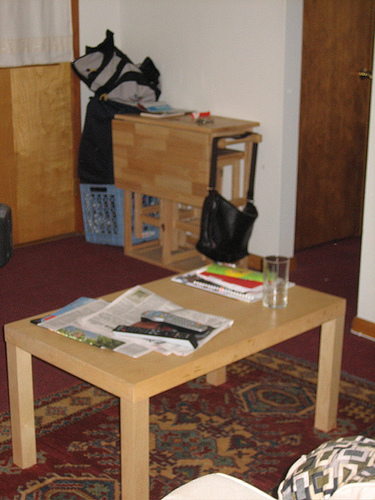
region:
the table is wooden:
[128, 459, 147, 490]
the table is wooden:
[130, 446, 153, 485]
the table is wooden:
[134, 458, 146, 463]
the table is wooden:
[128, 456, 146, 473]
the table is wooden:
[134, 461, 145, 466]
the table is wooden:
[127, 462, 143, 475]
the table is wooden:
[128, 467, 146, 480]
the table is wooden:
[135, 473, 144, 477]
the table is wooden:
[134, 463, 151, 470]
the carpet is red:
[229, 438, 240, 466]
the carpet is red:
[215, 471, 232, 478]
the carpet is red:
[228, 473, 248, 479]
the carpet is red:
[237, 441, 248, 458]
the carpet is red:
[243, 392, 257, 420]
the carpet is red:
[241, 388, 254, 412]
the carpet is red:
[253, 385, 266, 412]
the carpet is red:
[239, 448, 251, 457]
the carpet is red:
[203, 419, 217, 438]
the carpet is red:
[209, 425, 227, 446]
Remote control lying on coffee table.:
[140, 306, 224, 338]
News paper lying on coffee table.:
[35, 287, 227, 360]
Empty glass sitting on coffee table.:
[259, 250, 295, 313]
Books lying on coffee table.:
[170, 257, 292, 306]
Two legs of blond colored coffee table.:
[4, 335, 185, 498]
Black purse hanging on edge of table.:
[192, 129, 269, 266]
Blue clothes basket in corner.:
[73, 177, 175, 250]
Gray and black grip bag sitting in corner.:
[71, 31, 178, 109]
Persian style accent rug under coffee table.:
[54, 353, 373, 498]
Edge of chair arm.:
[159, 464, 308, 497]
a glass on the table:
[244, 247, 324, 342]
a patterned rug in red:
[200, 439, 277, 469]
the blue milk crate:
[40, 148, 166, 248]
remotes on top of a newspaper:
[91, 298, 239, 374]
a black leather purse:
[186, 124, 274, 295]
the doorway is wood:
[265, 26, 358, 154]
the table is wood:
[243, 259, 350, 440]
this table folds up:
[99, 108, 244, 211]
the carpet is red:
[4, 276, 85, 296]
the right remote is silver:
[90, 288, 224, 368]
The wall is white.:
[158, 28, 275, 89]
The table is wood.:
[48, 288, 351, 382]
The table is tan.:
[41, 253, 341, 403]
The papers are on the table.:
[40, 306, 224, 364]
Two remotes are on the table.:
[110, 294, 210, 371]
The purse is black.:
[198, 126, 267, 261]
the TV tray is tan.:
[115, 107, 246, 257]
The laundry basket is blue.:
[73, 183, 165, 244]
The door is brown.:
[305, 23, 359, 281]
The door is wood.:
[304, 85, 353, 281]